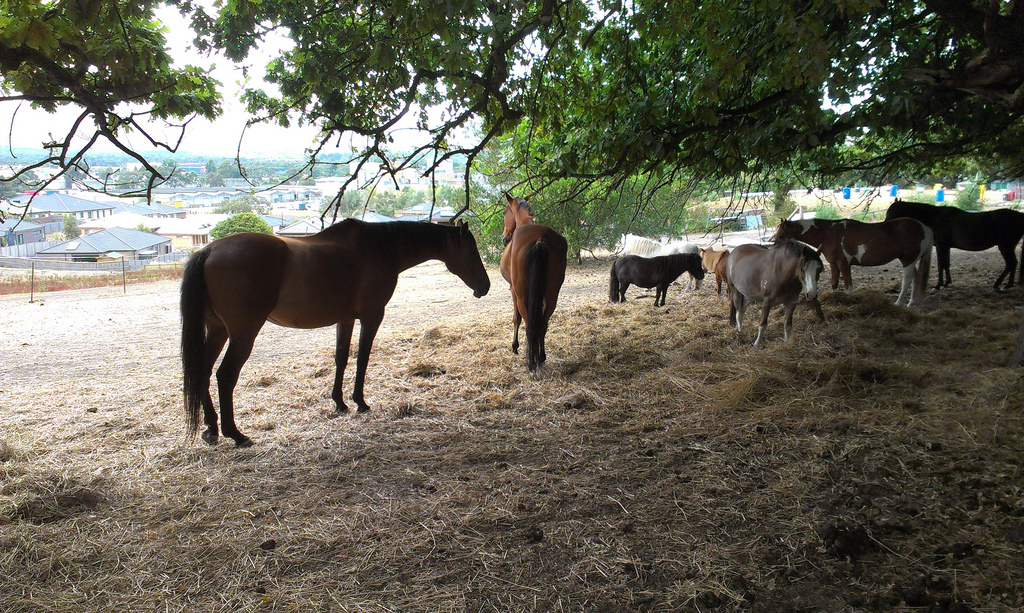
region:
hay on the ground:
[510, 468, 761, 539]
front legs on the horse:
[329, 327, 381, 410]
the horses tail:
[177, 294, 207, 409]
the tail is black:
[171, 294, 213, 430]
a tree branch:
[76, 108, 182, 195]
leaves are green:
[288, 57, 334, 92]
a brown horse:
[611, 256, 707, 296]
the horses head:
[440, 223, 491, 301]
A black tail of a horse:
[180, 240, 216, 455]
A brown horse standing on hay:
[167, 217, 494, 459]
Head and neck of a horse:
[388, 214, 502, 306]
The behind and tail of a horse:
[514, 225, 575, 377]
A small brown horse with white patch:
[721, 237, 827, 345]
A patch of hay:
[462, 440, 571, 535]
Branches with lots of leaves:
[6, 12, 207, 158]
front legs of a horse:
[331, 259, 408, 453]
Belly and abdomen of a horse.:
[252, 285, 380, 343]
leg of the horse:
[317, 367, 352, 412]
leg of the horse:
[598, 288, 628, 302]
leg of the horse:
[741, 318, 764, 344]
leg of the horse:
[719, 306, 755, 333]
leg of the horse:
[886, 287, 912, 308]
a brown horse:
[167, 193, 494, 440]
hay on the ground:
[71, 476, 239, 610]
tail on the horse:
[518, 240, 560, 361]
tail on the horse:
[175, 242, 205, 436]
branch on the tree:
[102, 130, 188, 192]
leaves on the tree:
[98, 29, 206, 110]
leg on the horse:
[343, 317, 385, 404]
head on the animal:
[788, 245, 831, 303]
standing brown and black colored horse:
[148, 189, 496, 445]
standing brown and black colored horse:
[484, 195, 580, 388]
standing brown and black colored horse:
[604, 241, 691, 331]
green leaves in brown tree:
[568, 63, 604, 109]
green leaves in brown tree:
[633, 7, 735, 128]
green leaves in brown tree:
[88, 40, 175, 92]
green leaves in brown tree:
[895, 75, 994, 152]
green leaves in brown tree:
[663, 43, 737, 98]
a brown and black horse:
[487, 184, 577, 377]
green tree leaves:
[469, 40, 644, 212]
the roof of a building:
[45, 227, 163, 254]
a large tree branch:
[424, 107, 519, 229]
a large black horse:
[604, 249, 710, 311]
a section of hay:
[254, 423, 637, 610]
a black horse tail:
[513, 239, 552, 370]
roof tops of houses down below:
[3, 184, 415, 261]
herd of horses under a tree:
[171, 194, 1022, 454]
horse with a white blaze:
[724, 243, 824, 358]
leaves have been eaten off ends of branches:
[12, 91, 624, 219]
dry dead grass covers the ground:
[0, 249, 1019, 608]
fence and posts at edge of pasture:
[0, 246, 238, 298]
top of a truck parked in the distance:
[704, 208, 768, 234]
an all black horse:
[606, 249, 704, 311]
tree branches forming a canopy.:
[2, 0, 1015, 200]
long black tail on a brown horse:
[176, 237, 208, 435]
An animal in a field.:
[135, 196, 486, 419]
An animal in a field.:
[483, 175, 569, 360]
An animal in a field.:
[723, 239, 847, 337]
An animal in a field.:
[773, 198, 928, 300]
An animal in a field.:
[878, 188, 1014, 278]